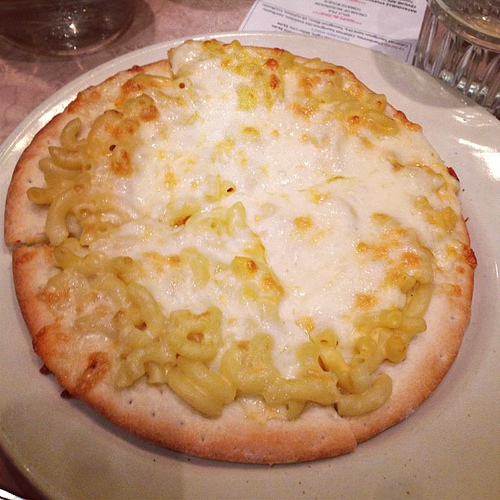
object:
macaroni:
[113, 285, 147, 321]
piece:
[0, 32, 469, 465]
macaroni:
[168, 358, 234, 417]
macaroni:
[333, 366, 390, 419]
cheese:
[69, 42, 450, 380]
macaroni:
[345, 99, 391, 136]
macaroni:
[26, 175, 84, 245]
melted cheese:
[115, 90, 387, 349]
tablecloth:
[1, 56, 39, 111]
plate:
[0, 25, 499, 500]